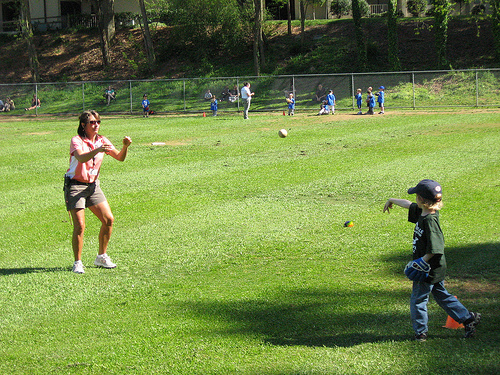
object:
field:
[2, 104, 500, 373]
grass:
[0, 104, 500, 375]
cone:
[441, 295, 467, 330]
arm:
[70, 137, 99, 164]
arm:
[102, 136, 128, 163]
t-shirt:
[406, 200, 449, 286]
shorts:
[63, 178, 107, 211]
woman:
[240, 81, 255, 119]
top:
[240, 86, 251, 99]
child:
[375, 86, 386, 115]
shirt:
[376, 91, 385, 103]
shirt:
[355, 94, 363, 105]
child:
[325, 89, 336, 115]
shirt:
[326, 94, 336, 105]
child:
[209, 95, 218, 117]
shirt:
[210, 100, 218, 111]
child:
[285, 93, 296, 116]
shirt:
[287, 98, 295, 109]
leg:
[87, 190, 116, 256]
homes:
[0, 0, 143, 33]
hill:
[0, 0, 500, 102]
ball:
[277, 129, 288, 139]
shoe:
[463, 311, 483, 339]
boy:
[379, 176, 487, 345]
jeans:
[409, 277, 473, 337]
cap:
[406, 178, 443, 202]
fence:
[0, 68, 500, 115]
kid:
[354, 88, 363, 115]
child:
[365, 90, 376, 115]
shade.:
[165, 238, 500, 337]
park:
[0, 0, 500, 375]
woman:
[105, 85, 117, 107]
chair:
[94, 97, 117, 105]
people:
[24, 93, 42, 112]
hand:
[382, 199, 393, 215]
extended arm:
[389, 197, 420, 212]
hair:
[77, 110, 101, 140]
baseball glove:
[402, 257, 431, 283]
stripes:
[0, 135, 500, 345]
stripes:
[0, 115, 278, 159]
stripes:
[0, 112, 493, 219]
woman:
[60, 109, 135, 275]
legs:
[408, 279, 435, 337]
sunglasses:
[83, 120, 102, 125]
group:
[283, 83, 388, 118]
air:
[0, 0, 499, 85]